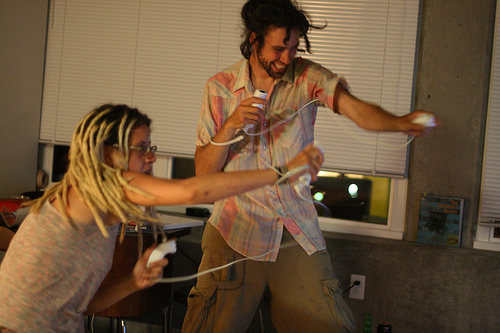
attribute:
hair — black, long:
[240, 2, 327, 60]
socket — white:
[349, 274, 366, 301]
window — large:
[37, 1, 420, 243]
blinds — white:
[41, 0, 421, 183]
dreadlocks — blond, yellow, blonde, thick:
[46, 102, 169, 239]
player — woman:
[2, 103, 322, 329]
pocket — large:
[180, 288, 213, 331]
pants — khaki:
[182, 208, 360, 332]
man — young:
[182, 1, 437, 332]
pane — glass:
[171, 154, 392, 227]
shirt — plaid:
[202, 57, 347, 243]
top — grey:
[1, 181, 120, 332]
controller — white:
[246, 88, 267, 132]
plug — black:
[353, 280, 362, 286]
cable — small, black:
[337, 279, 358, 302]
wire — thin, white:
[161, 240, 329, 283]